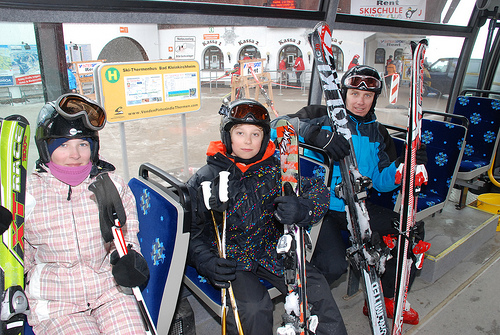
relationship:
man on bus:
[180, 95, 351, 335] [42, 10, 492, 322]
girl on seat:
[2, 88, 148, 335] [118, 159, 195, 333]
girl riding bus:
[2, 88, 148, 335] [1, 1, 494, 330]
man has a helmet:
[180, 95, 351, 335] [213, 96, 274, 163]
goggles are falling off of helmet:
[56, 93, 108, 130] [34, 90, 97, 142]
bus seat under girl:
[141, 190, 411, 221] [2, 88, 148, 335]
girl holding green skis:
[2, 88, 148, 335] [1, 112, 28, 332]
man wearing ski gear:
[270, 62, 426, 325] [277, 100, 409, 295]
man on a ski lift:
[180, 95, 351, 335] [16, 80, 427, 315]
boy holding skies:
[191, 98, 334, 333] [269, 112, 321, 333]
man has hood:
[180, 95, 331, 329] [204, 136, 274, 171]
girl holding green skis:
[3, 88, 175, 334] [1, 112, 28, 332]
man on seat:
[180, 95, 351, 335] [118, 159, 195, 333]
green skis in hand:
[1, 112, 28, 332] [0, 204, 15, 234]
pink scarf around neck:
[17, 157, 159, 218] [37, 162, 97, 185]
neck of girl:
[37, 162, 97, 185] [2, 88, 148, 335]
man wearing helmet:
[180, 95, 351, 335] [217, 96, 271, 163]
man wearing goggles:
[180, 95, 351, 335] [229, 102, 269, 122]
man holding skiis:
[270, 62, 426, 325] [308, 20, 428, 332]